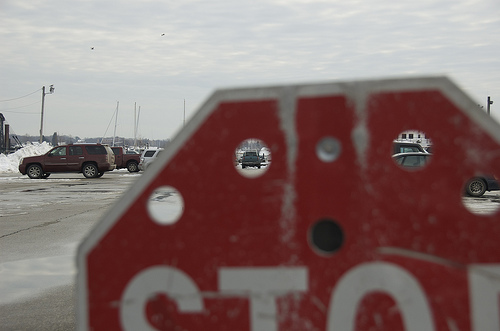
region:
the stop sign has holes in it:
[131, 96, 498, 259]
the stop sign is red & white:
[168, 84, 493, 175]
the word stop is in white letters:
[103, 232, 498, 327]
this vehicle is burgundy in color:
[13, 131, 120, 197]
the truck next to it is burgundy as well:
[103, 140, 137, 177]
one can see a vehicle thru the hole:
[229, 145, 272, 170]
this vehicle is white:
[134, 138, 174, 175]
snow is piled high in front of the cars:
[1, 142, 66, 212]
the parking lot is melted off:
[8, 177, 96, 249]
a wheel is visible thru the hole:
[458, 175, 499, 211]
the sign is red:
[70, 72, 499, 329]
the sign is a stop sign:
[63, 72, 498, 329]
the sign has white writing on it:
[114, 256, 499, 329]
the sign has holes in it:
[142, 127, 499, 229]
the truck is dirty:
[110, 143, 145, 174]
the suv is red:
[18, 142, 116, 182]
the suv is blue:
[233, 145, 274, 178]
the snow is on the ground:
[1, 135, 168, 182]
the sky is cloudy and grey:
[0, 0, 499, 145]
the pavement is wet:
[0, 171, 499, 327]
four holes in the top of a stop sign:
[148, 127, 497, 221]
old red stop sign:
[75, 70, 492, 327]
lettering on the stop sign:
[122, 258, 492, 329]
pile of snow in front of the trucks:
[2, 140, 50, 172]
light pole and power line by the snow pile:
[0, 85, 48, 135]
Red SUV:
[20, 143, 112, 179]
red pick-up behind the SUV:
[112, 145, 139, 172]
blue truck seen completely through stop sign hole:
[239, 147, 264, 169]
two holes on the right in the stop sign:
[391, 130, 498, 217]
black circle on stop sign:
[309, 218, 344, 254]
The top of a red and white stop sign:
[70, 74, 497, 329]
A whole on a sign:
[146, 170, 190, 241]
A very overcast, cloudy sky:
[75, 21, 319, 78]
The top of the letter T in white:
[215, 254, 316, 329]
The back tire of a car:
[467, 174, 490, 201]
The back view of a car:
[235, 147, 264, 172]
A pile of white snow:
[13, 137, 53, 152]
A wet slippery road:
[26, 181, 75, 258]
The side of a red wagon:
[17, 137, 122, 182]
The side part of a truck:
[111, 146, 141, 175]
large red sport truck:
[11, 131, 125, 186]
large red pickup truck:
[84, 133, 151, 183]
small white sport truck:
[121, 133, 181, 177]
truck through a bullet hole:
[220, 122, 282, 188]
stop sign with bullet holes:
[14, 44, 499, 328]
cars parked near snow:
[0, 115, 184, 193]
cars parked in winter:
[1, 107, 173, 184]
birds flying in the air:
[76, 19, 186, 67]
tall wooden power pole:
[26, 73, 64, 147]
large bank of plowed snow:
[0, 127, 67, 188]